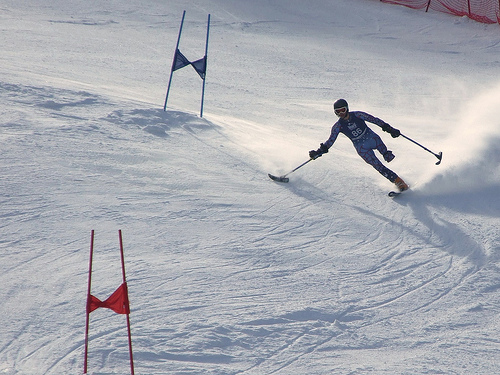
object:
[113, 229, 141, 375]
poles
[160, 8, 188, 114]
poles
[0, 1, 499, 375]
race course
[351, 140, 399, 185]
leg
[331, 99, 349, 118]
helmet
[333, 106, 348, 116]
goggles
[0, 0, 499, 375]
snow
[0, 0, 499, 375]
hill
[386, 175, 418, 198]
ski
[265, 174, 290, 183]
skiis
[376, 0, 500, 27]
fence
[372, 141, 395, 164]
half leg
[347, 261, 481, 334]
tracks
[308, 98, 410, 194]
person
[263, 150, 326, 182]
ski poles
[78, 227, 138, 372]
flag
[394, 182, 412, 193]
foot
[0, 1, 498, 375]
ground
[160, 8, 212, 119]
flag